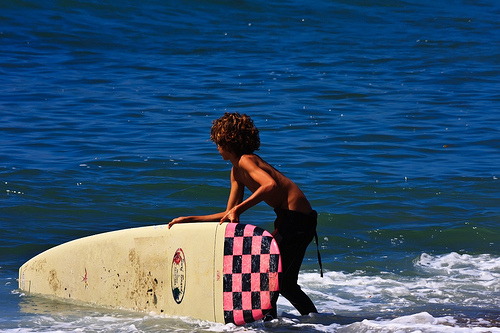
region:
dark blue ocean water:
[266, 50, 436, 129]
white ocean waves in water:
[374, 268, 457, 323]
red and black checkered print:
[226, 228, 265, 288]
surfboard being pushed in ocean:
[5, 219, 304, 323]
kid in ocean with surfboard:
[196, 97, 341, 326]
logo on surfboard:
[160, 237, 198, 314]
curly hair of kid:
[193, 96, 277, 171]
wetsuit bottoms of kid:
[261, 200, 341, 332]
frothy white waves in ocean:
[326, 265, 433, 330]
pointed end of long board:
[0, 258, 209, 325]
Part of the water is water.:
[350, 255, 497, 327]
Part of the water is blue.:
[327, 55, 477, 165]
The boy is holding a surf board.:
[20, 75, 355, 330]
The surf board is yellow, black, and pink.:
[16, 212, 296, 327]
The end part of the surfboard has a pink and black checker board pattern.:
[220, 206, 281, 328]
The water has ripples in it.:
[55, 11, 467, 81]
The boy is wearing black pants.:
[255, 196, 337, 322]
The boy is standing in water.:
[185, 85, 331, 330]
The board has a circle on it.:
[155, 232, 196, 307]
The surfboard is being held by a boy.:
[146, 200, 287, 247]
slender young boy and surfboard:
[109, 81, 378, 324]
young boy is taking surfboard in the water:
[1, 85, 345, 327]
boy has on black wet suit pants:
[244, 196, 344, 323]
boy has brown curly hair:
[207, 108, 266, 163]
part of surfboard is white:
[18, 202, 214, 324]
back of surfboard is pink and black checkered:
[213, 219, 289, 329]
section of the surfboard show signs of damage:
[51, 252, 168, 315]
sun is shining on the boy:
[184, 127, 316, 226]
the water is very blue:
[301, 71, 456, 216]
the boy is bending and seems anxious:
[166, 90, 344, 325]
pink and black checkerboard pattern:
[221, 216, 280, 329]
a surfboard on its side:
[12, 213, 297, 326]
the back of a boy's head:
[207, 105, 266, 170]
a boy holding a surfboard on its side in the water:
[11, 105, 358, 329]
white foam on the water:
[330, 238, 498, 331]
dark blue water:
[15, 17, 488, 99]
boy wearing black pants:
[185, 109, 345, 329]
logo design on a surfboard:
[149, 232, 200, 307]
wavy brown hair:
[206, 107, 266, 153]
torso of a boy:
[227, 151, 324, 222]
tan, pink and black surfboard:
[18, 223, 283, 325]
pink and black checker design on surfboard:
[223, 221, 282, 323]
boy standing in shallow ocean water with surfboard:
[14, 113, 319, 325]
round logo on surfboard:
[165, 246, 190, 303]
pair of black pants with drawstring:
[268, 209, 325, 316]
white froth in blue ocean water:
[415, 250, 499, 292]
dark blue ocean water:
[64, 86, 188, 165]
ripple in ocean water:
[323, 132, 410, 146]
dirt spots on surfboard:
[117, 246, 163, 309]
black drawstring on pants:
[312, 231, 327, 279]